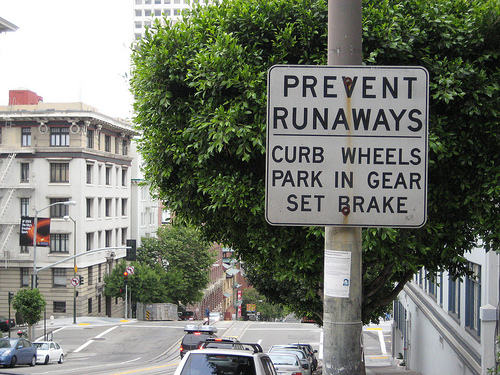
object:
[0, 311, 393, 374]
street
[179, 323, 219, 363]
vehicle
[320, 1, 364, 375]
pole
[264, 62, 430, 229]
sign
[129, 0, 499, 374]
tree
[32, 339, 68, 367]
car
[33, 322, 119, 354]
line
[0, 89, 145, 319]
building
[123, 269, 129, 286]
traffic signal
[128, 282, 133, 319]
pole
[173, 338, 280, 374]
vehicle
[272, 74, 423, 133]
prevent runaways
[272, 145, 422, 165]
curb wheels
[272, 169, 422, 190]
park in gear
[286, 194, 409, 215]
set brake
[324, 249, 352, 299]
paper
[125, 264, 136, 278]
sign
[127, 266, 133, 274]
no left turn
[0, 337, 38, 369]
vehicle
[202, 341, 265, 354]
luggage rack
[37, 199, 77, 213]
street lamp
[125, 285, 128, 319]
pole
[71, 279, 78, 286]
no left turn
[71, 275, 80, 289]
sign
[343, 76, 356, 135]
rust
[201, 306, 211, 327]
person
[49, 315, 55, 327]
fire hydrant